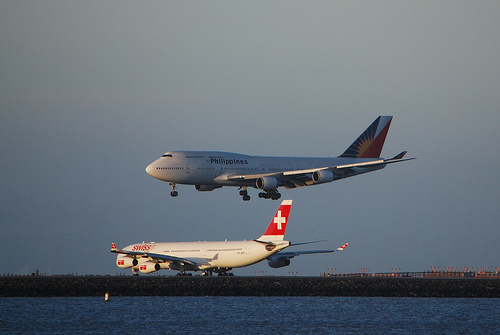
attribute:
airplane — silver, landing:
[143, 110, 423, 204]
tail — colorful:
[338, 113, 395, 159]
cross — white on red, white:
[273, 211, 287, 232]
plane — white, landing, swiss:
[106, 197, 352, 278]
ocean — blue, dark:
[2, 295, 499, 335]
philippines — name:
[208, 155, 253, 168]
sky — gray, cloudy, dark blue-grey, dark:
[2, 0, 499, 203]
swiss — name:
[132, 243, 155, 253]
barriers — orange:
[253, 263, 499, 275]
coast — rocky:
[4, 273, 500, 298]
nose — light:
[141, 159, 168, 179]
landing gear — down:
[166, 185, 285, 203]